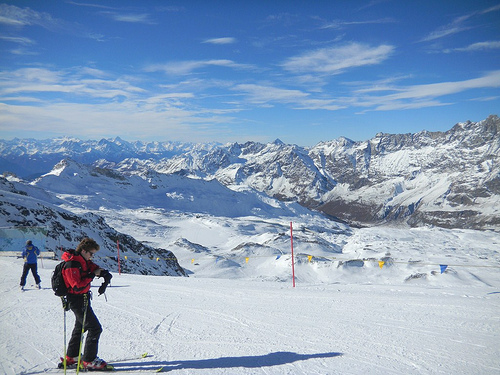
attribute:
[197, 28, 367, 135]
sky — blue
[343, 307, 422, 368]
snow — white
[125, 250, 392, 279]
flags — yellow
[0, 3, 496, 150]
sky — blue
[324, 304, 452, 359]
snow — white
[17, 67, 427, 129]
clouds — white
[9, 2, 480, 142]
sky — blue, white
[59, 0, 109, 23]
shoes — red, ski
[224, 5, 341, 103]
sky — blue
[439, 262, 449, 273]
flag — blue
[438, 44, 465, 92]
clouds — white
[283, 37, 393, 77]
cloud — white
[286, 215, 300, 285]
pole — red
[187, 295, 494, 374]
snow — covering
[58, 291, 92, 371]
poles — ski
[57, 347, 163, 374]
ski shoes — red, white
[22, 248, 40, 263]
jacket — blue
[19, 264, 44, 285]
pants — black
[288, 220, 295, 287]
pole — red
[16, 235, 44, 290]
person — skiing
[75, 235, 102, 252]
hair — short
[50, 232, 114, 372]
man — black, preparing to ski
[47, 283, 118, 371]
ski poles — yellow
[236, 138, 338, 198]
mountain — snow covered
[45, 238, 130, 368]
person — wearing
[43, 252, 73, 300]
backpack — black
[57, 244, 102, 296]
jacket — red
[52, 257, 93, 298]
backpack — black